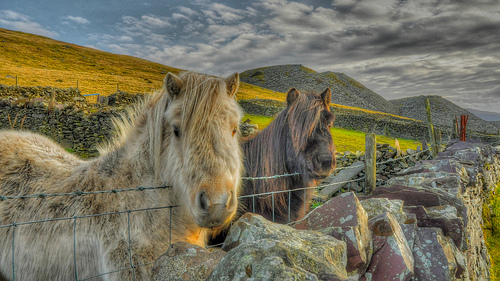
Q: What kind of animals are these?
A: Horses.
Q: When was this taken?
A: Daytime.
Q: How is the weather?
A: Cloudy.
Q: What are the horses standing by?
A: Fence.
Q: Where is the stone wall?
A: Running along the fence.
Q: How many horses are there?
A: 2.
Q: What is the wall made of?
A: Stone.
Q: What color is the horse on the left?
A: Brown and white.